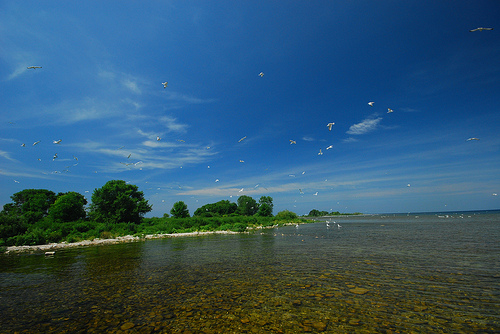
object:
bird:
[238, 136, 247, 143]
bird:
[52, 139, 62, 144]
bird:
[51, 139, 62, 143]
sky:
[0, 0, 499, 218]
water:
[0, 210, 499, 334]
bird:
[386, 109, 394, 115]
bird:
[469, 27, 492, 33]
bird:
[258, 72, 264, 78]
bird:
[159, 81, 169, 88]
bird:
[161, 82, 168, 88]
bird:
[258, 71, 263, 76]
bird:
[53, 140, 62, 144]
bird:
[288, 140, 297, 145]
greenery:
[0, 179, 363, 247]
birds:
[0, 26, 499, 255]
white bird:
[326, 123, 335, 131]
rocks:
[0, 212, 499, 332]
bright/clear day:
[1, 2, 500, 331]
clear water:
[0, 214, 500, 333]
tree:
[88, 180, 153, 222]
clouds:
[0, 50, 500, 215]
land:
[301, 208, 367, 218]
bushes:
[0, 180, 360, 246]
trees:
[0, 179, 272, 226]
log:
[44, 251, 56, 255]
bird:
[327, 122, 335, 131]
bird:
[367, 102, 375, 107]